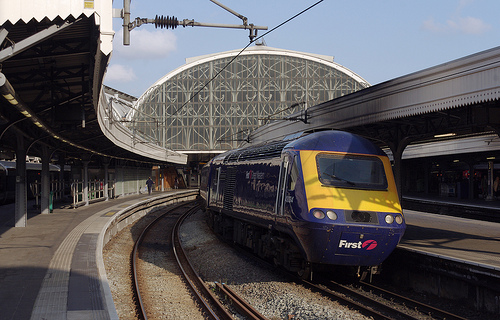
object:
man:
[145, 177, 155, 196]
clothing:
[146, 180, 154, 196]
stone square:
[48, 231, 103, 301]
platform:
[1, 187, 197, 320]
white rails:
[80, 160, 109, 206]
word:
[338, 240, 362, 250]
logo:
[361, 239, 377, 250]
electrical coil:
[153, 14, 179, 30]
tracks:
[130, 198, 467, 320]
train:
[195, 128, 407, 282]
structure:
[123, 46, 370, 155]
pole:
[120, 12, 268, 46]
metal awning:
[0, 49, 245, 189]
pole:
[39, 137, 50, 215]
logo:
[338, 239, 378, 250]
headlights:
[312, 209, 404, 225]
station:
[396, 208, 499, 276]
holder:
[119, 0, 268, 46]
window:
[316, 153, 389, 190]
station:
[1, 11, 500, 320]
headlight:
[326, 210, 338, 220]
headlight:
[385, 214, 395, 224]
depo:
[338, 71, 451, 189]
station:
[385, 49, 497, 195]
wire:
[240, 15, 299, 52]